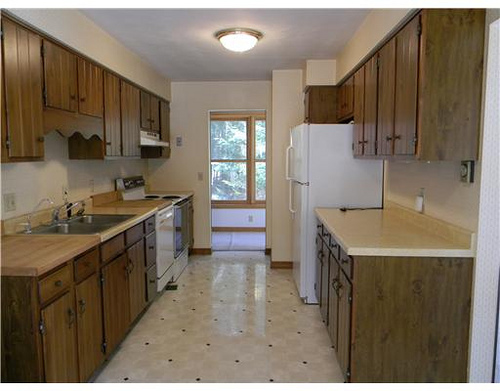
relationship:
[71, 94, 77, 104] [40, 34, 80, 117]
knob on cabinet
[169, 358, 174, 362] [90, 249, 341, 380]
black circle on floor tile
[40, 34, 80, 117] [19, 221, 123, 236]
cabinet handing above sink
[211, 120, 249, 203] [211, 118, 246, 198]
window facing trees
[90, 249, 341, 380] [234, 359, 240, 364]
tile has black circle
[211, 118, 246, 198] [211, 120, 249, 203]
trees behind window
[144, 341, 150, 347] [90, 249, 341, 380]
black circle on tile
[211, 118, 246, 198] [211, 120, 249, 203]
trees outside of window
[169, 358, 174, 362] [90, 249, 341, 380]
black circle on tile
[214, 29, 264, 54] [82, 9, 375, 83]
light hanging on ceiling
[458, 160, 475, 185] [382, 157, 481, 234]
switch attached to wall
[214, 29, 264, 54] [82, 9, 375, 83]
light on ceiling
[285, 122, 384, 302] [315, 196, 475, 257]
refrigerator next to countertop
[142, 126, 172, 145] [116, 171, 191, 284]
hood above range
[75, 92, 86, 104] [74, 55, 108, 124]
knob on cabinet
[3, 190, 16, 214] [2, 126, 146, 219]
light switch on wall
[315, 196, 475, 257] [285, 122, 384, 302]
countertop next to refrigerator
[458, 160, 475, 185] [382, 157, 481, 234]
switch on wall